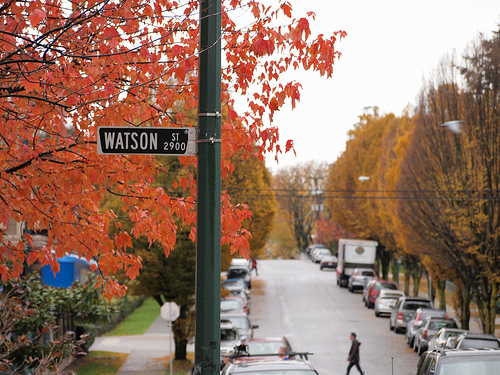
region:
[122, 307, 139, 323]
short brown and green grass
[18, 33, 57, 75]
orange leaves on brown trees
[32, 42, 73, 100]
orange leaves on brown trees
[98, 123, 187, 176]
street sign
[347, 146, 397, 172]
orange leaves on brown trees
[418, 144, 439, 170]
orange leaves on brown trees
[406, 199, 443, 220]
orange leaves on brown trees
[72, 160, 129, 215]
orange leaves on brown trees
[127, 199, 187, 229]
orange leaves on brown trees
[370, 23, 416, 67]
white clouds in blue sky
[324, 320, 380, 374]
man crossing the street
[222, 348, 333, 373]
car with rack on the roof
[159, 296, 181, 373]
back of stop sign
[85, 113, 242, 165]
watson street sign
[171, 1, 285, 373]
tall metal pole with street sign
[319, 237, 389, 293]
large box truck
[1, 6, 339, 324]
tree with bright orange leaves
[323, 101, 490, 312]
trees turning brown and orange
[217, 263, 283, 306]
leaves around cars in street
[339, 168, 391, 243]
light pole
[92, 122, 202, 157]
Street is Watson St.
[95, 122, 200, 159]
Sign is shaped like a rectangle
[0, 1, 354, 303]
Leaves are orange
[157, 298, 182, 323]
Back of sign is white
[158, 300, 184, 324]
Sign is shaped like an octagon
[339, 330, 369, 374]
Man is walking across the street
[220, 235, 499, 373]
Cars are parked along the street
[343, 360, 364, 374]
Man is wearing pants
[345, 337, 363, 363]
Man is wearing a jacket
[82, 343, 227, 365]
Dead leaves on the ground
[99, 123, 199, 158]
sign telling the name of the street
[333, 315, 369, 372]
a person with hooded jacket crosses the road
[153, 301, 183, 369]
rear view of stop sign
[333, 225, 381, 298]
a parked panel truck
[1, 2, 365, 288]
glowing autumn leaves on tree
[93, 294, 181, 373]
sidewalk edged with green grass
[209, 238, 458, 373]
numerous cars line the street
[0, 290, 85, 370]
part of fencing along sidewalk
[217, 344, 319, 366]
rack mounted to car top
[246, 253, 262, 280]
a person in red crossing in the distance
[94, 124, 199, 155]
street sign on a pole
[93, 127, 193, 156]
sign denoting 2900 block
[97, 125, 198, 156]
sign denoting Watson Street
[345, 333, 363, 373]
young man who is jaywalking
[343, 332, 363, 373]
young man wearing a hoodie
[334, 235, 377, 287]
truck parked on the street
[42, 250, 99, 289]
blue object behind the leaves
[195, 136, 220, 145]
clamp on the pole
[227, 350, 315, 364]
roof rack on a vehicle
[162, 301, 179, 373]
back of a stop sign